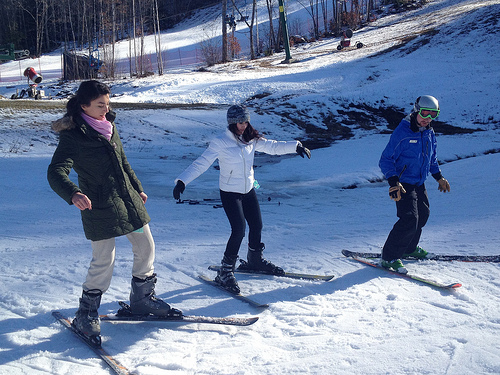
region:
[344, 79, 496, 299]
a man with skis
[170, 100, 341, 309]
a young girl with skis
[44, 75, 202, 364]
a woman wearing skis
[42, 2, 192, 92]
trees with no leaves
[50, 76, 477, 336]
3 people skiing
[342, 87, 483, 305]
a skier with green goggles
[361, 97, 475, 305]
a skier with a blue jacket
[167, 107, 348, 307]
a skier with a white jacket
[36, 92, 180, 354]
a woman with a pink scarf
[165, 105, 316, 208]
a girl with black gloves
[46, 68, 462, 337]
three people learning to ski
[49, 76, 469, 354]
people learning to wedge skis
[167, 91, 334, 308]
skier with a white jacket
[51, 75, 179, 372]
skier with a pink scarf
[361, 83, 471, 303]
skier with green goggles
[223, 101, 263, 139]
girl with a knitted hat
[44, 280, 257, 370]
skis in a wedge formation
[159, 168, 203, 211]
girl wearing black gloves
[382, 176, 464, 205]
padded tan gloves for winter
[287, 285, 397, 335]
ski tracks in the snow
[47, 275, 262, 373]
pair of black skis and snowboots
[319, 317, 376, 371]
patch of white snow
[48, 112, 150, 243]
black quilted snow coat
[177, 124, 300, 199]
white quilted snow jacket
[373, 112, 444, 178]
purple snow jacket with hood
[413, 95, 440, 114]
silver hard helmet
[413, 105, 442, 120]
green and red goggles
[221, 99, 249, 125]
black and grey knit cap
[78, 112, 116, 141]
pink layered cotton scarf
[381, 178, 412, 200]
one tan and black glove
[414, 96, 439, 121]
Man with goggles on head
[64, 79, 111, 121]
Woman has black hair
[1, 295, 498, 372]
Snow is on the ground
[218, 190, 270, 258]
woman has on black pants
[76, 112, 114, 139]
woman has on pink scarf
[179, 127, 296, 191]
woman has on white jacket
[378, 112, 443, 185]
man has on blue jacket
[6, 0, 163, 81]
trees are narrow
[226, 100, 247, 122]
the woman has a gray head covering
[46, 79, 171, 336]
woman is skiing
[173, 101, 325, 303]
Girl with white jacket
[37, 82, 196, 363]
Woman with white coat and pink scarf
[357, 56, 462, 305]
Man with blue jacket and snow glasses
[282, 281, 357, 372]
Tracks in the snow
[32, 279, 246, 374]
Ski shoes in snow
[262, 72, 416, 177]
Melted snow on the bank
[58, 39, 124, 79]
Small rundown cabin in woods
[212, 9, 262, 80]
Tall tree trunk in background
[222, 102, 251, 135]
Lady is wearing blue hat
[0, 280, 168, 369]
Shadow from skier